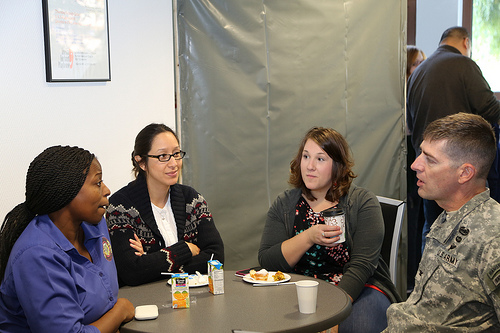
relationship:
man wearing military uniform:
[383, 113, 499, 331] [382, 188, 500, 331]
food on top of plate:
[249, 269, 285, 281] [243, 271, 291, 284]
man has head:
[383, 113, 499, 331] [411, 112, 495, 199]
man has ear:
[383, 113, 499, 331] [459, 163, 475, 185]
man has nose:
[383, 113, 499, 331] [411, 155, 423, 173]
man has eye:
[383, 113, 499, 331] [427, 157, 435, 161]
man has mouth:
[383, 113, 499, 331] [417, 177, 426, 188]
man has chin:
[383, 113, 499, 331] [417, 186, 435, 198]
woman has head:
[259, 127, 402, 332] [290, 127, 348, 189]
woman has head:
[106, 124, 223, 284] [134, 123, 185, 184]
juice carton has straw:
[172, 275, 190, 308] [162, 272, 178, 275]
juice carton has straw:
[208, 260, 224, 294] [209, 253, 214, 263]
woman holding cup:
[259, 127, 402, 332] [324, 210, 347, 244]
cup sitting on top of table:
[296, 280, 319, 315] [120, 269, 351, 331]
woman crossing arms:
[106, 124, 223, 284] [108, 200, 225, 284]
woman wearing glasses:
[106, 124, 223, 284] [149, 150, 187, 162]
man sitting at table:
[379, 111, 500, 332] [120, 269, 351, 331]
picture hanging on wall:
[44, 1, 111, 81] [2, 1, 175, 221]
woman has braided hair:
[3, 146, 136, 331] [2, 146, 94, 278]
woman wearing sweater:
[106, 124, 223, 284] [108, 173, 225, 285]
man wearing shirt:
[408, 28, 499, 155] [408, 45, 500, 157]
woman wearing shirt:
[3, 146, 136, 331] [2, 216, 117, 331]